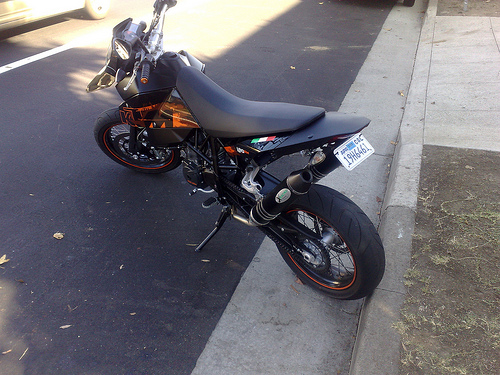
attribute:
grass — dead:
[390, 174, 498, 373]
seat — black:
[174, 66, 324, 137]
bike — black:
[98, 25, 328, 253]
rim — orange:
[279, 207, 363, 297]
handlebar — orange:
[137, 56, 154, 84]